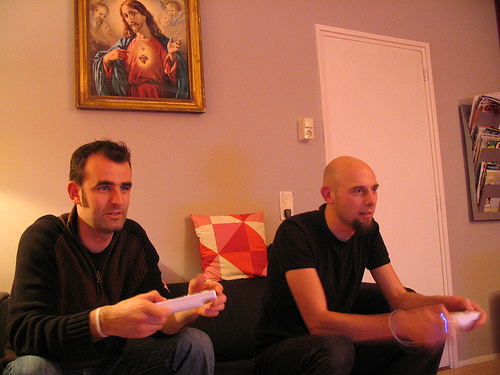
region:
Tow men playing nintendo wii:
[0, 131, 487, 373]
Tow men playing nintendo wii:
[3, 135, 493, 370]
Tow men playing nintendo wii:
[4, 135, 489, 370]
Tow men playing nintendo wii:
[6, 132, 492, 374]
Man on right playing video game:
[256, 148, 480, 362]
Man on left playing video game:
[20, 136, 228, 371]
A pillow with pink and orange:
[185, 210, 270, 280]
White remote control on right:
[423, 280, 480, 372]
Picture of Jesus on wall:
[63, 3, 223, 118]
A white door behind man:
[310, 9, 448, 163]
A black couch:
[203, 246, 270, 343]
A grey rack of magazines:
[455, 89, 499, 219]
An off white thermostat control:
[296, 107, 316, 149]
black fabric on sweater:
[36, 240, 61, 264]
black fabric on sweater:
[29, 273, 62, 305]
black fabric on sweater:
[25, 308, 57, 330]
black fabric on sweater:
[57, 316, 87, 341]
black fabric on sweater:
[104, 274, 134, 296]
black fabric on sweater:
[125, 251, 147, 284]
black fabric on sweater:
[127, 238, 145, 250]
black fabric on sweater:
[144, 250, 164, 273]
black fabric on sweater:
[139, 270, 159, 285]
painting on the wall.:
[120, 21, 168, 68]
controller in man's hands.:
[162, 287, 210, 314]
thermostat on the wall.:
[294, 110, 314, 148]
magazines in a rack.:
[477, 158, 492, 197]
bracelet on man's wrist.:
[92, 305, 100, 335]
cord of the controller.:
[383, 306, 402, 342]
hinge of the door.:
[420, 60, 432, 92]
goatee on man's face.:
[349, 217, 376, 234]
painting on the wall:
[64, 0, 215, 115]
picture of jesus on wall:
[95, 3, 189, 96]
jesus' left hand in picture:
[159, 35, 185, 61]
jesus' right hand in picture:
[106, 43, 129, 69]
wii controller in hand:
[145, 289, 218, 318]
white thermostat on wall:
[292, 110, 330, 147]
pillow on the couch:
[188, 214, 276, 280]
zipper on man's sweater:
[90, 270, 110, 287]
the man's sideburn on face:
[75, 182, 91, 205]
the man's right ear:
[317, 181, 336, 205]